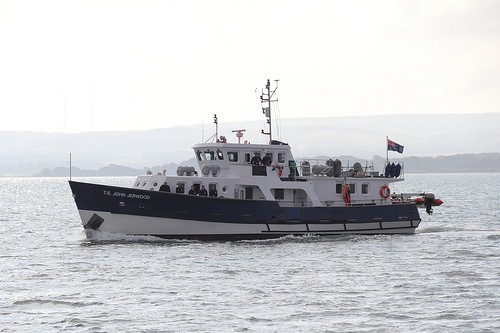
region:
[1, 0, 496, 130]
bright light over ocean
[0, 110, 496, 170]
slope of mountains in distance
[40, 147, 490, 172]
narrow edge of low land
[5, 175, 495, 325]
calm gray water of sea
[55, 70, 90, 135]
outline of poles over mountain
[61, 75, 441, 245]
blue and white boat floating on water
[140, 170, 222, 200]
people on side by windows and doors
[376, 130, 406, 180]
flag flying over upright cylinders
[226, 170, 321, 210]
extended open side panel in middle of boat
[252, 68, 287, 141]
pole with instruments for measurements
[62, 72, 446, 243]
a cruiseship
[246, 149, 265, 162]
a person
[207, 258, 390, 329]
the water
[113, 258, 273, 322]
the oceans water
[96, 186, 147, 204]
writing on the boat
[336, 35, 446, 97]
the clouds in the sky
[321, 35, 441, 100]
the sky is clear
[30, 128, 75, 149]
mountains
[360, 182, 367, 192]
window on the boat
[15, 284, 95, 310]
a small wave in the water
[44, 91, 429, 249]
white boat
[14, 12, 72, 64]
white clouds in blue sky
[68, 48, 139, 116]
white clouds in blue sky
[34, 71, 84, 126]
white clouds in blue sky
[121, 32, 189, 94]
white clouds in blue sky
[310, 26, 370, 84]
white clouds in blue sky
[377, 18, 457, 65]
white clouds in blue sky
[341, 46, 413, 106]
white clouds in blue sky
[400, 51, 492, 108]
white clouds in blue sky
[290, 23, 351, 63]
white clouds in blue sky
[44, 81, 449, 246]
boat in water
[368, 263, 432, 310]
white and blue ocean waves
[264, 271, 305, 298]
white and blue ocean waves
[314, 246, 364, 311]
white and blue ocean waves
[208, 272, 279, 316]
white and blue ocean waves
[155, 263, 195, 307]
white and blue ocean waves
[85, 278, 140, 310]
white and blue ocean waves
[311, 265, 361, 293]
white and blue ocean waves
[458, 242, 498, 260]
white and blue ocean waves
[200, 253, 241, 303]
white and blue ocean waves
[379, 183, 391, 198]
round red safety device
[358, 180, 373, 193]
window on large boat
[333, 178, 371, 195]
row of windows on boat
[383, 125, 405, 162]
flag on back of boat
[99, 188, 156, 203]
white letters on side of boat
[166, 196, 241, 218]
blue stripe on boat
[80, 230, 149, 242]
water splashing on front of boat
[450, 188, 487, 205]
ripples in dark water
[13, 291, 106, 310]
waves in dark water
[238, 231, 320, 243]
waves around large boat